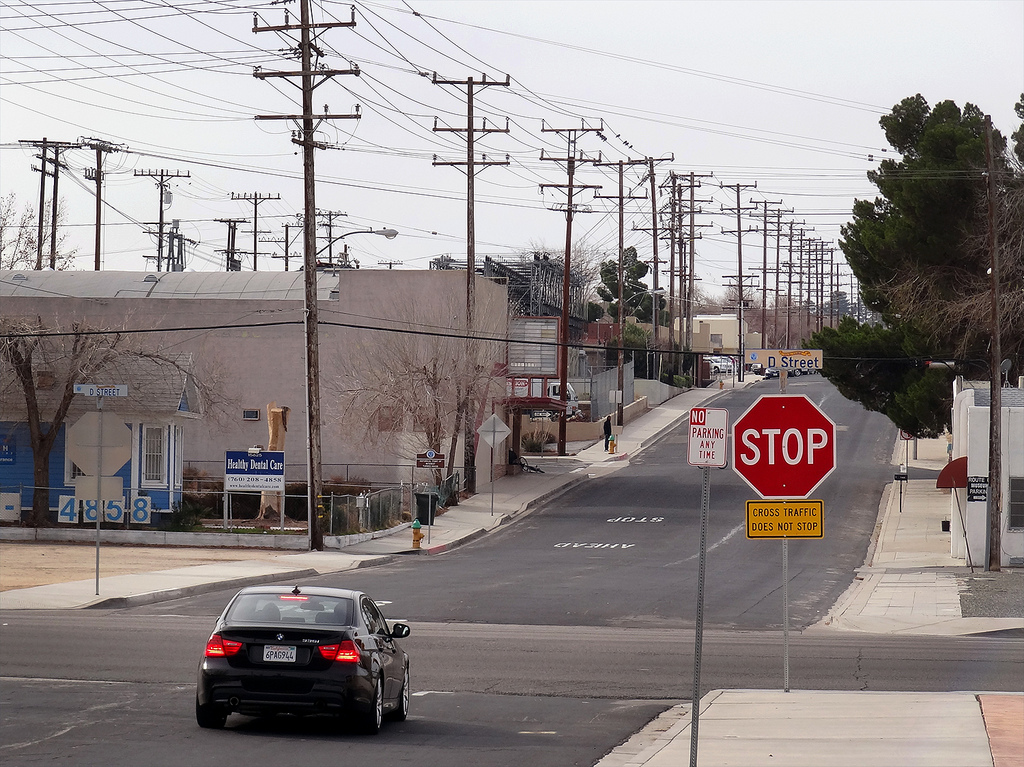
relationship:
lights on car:
[169, 594, 451, 705] [132, 551, 437, 696]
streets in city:
[104, 274, 554, 663] [346, 447, 640, 720]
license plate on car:
[238, 622, 342, 696] [192, 555, 424, 713]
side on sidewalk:
[648, 670, 713, 763] [633, 719, 683, 745]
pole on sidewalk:
[674, 607, 718, 757] [668, 689, 800, 759]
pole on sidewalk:
[476, 404, 507, 519] [24, 374, 766, 694]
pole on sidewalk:
[530, 424, 576, 464] [1, 357, 777, 671]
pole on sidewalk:
[597, 136, 643, 458] [1, 365, 769, 649]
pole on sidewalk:
[714, 167, 749, 392] [24, 374, 766, 694]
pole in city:
[241, 0, 389, 590] [1, 1, 1017, 749]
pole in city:
[420, 61, 524, 552] [1, 1, 1017, 749]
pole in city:
[526, 102, 624, 476] [1, 1, 1017, 749]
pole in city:
[569, 145, 658, 476] [1, 1, 1017, 749]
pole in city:
[614, 130, 692, 407] [1, 1, 1017, 749]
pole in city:
[12, 128, 86, 306] [1, 1, 1017, 749]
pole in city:
[120, 152, 201, 273] [1, 1, 1017, 749]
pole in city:
[225, 173, 293, 280] [1, 1, 1017, 749]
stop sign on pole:
[727, 388, 846, 505] [744, 487, 794, 675]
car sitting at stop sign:
[186, 571, 426, 753] [716, 363, 844, 502]